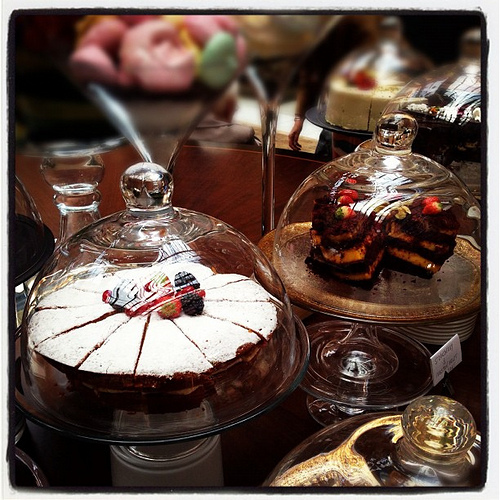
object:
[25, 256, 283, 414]
cake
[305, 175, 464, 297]
cake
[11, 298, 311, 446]
platter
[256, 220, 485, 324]
platter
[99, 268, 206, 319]
fruit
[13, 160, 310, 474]
lid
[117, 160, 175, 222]
handle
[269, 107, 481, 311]
lid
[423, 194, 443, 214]
strawberry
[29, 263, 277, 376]
frosting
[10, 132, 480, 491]
table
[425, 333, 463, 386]
sign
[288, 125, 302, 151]
hand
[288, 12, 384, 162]
person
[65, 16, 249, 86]
dessert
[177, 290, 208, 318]
berry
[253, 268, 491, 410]
cake stand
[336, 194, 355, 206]
strawberry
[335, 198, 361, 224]
strawberry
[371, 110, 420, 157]
knob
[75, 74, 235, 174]
cup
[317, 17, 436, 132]
container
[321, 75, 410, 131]
pastry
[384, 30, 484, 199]
container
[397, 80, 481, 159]
pastry